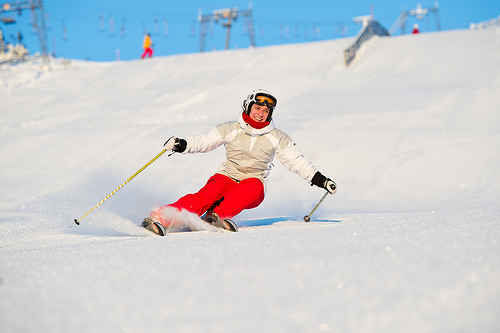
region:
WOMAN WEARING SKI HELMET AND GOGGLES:
[233, 86, 291, 133]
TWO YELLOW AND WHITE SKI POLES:
[53, 136, 361, 230]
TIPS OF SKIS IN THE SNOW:
[128, 213, 251, 237]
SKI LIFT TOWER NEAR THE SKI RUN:
[177, 6, 290, 56]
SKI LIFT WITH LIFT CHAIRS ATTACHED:
[15, 5, 375, 52]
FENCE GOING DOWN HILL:
[333, 20, 397, 70]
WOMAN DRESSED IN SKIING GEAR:
[148, 85, 346, 237]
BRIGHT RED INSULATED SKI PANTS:
[143, 175, 277, 229]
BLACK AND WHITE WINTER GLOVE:
[307, 165, 342, 198]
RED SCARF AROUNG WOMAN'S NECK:
[203, 111, 293, 141]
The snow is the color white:
[370, 111, 459, 271]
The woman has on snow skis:
[128, 205, 244, 238]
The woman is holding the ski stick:
[300, 171, 342, 226]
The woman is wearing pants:
[146, 170, 270, 225]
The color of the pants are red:
[187, 166, 259, 217]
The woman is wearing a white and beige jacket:
[179, 120, 321, 191]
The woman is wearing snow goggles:
[243, 85, 279, 111]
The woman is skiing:
[36, 58, 361, 280]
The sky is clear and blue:
[46, 3, 120, 45]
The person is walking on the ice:
[130, 23, 165, 62]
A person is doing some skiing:
[0, 13, 473, 303]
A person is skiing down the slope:
[11, 27, 487, 299]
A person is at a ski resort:
[0, 5, 490, 315]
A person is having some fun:
[21, 30, 486, 302]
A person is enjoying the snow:
[11, 30, 496, 310]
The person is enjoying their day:
[42, 30, 493, 312]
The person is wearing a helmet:
[16, 35, 481, 298]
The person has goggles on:
[27, 37, 453, 298]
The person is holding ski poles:
[15, 38, 486, 304]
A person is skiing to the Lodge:
[15, 25, 490, 310]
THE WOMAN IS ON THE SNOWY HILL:
[58, 80, 349, 242]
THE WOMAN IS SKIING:
[58, 82, 363, 248]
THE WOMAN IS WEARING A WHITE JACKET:
[162, 112, 332, 197]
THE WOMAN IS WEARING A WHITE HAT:
[236, 85, 279, 126]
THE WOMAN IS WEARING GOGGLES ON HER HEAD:
[246, 90, 279, 110]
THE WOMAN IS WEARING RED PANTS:
[170, 170, 270, 230]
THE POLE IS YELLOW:
[56, 136, 182, 241]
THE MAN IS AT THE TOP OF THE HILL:
[117, 22, 160, 67]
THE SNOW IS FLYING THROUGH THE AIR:
[3, 151, 154, 267]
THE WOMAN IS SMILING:
[247, 108, 269, 130]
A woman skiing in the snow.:
[66, 85, 336, 226]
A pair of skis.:
[135, 195, 237, 240]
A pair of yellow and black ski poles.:
[56, 130, 327, 221]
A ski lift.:
[7, 5, 438, 55]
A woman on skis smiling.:
[67, 79, 340, 242]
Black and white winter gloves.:
[160, 135, 340, 192]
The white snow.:
[2, 32, 496, 331]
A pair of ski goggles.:
[251, 91, 278, 108]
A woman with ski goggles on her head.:
[157, 82, 289, 243]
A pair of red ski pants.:
[152, 170, 266, 222]